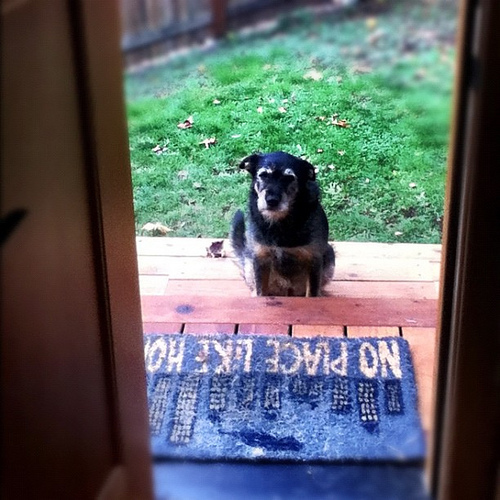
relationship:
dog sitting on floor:
[231, 152, 337, 297] [135, 236, 442, 500]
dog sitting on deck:
[231, 152, 337, 297] [136, 234, 443, 492]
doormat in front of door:
[140, 332, 426, 465] [3, 1, 193, 493]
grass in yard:
[138, 47, 440, 234] [120, 0, 462, 243]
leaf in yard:
[176, 115, 194, 133] [129, 12, 446, 237]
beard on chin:
[247, 211, 299, 226] [262, 207, 286, 225]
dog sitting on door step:
[233, 152, 341, 297] [141, 235, 433, 319]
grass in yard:
[124, 4, 460, 243] [128, 12, 434, 233]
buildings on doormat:
[158, 353, 404, 450] [140, 332, 426, 465]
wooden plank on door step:
[143, 294, 443, 326] [136, 294, 451, 468]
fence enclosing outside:
[120, 3, 215, 35] [150, 4, 431, 442]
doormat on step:
[140, 321, 440, 450] [148, 272, 436, 332]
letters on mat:
[146, 338, 404, 381] [142, 332, 439, 468]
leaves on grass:
[326, 47, 430, 85] [270, 74, 458, 179]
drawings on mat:
[147, 368, 424, 469] [142, 332, 439, 468]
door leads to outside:
[0, 1, 158, 498] [120, 4, 432, 465]